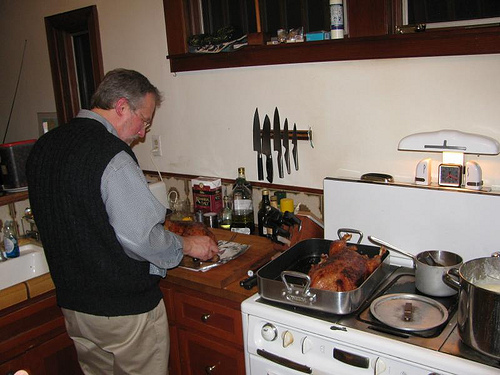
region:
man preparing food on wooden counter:
[23, 65, 243, 372]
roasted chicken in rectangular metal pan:
[257, 220, 390, 317]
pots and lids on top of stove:
[367, 229, 497, 371]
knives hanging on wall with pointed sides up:
[250, 105, 315, 185]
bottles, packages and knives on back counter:
[157, 170, 323, 245]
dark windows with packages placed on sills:
[160, 3, 499, 75]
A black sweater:
[41, 119, 112, 296]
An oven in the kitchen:
[277, 264, 382, 371]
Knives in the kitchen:
[241, 105, 301, 163]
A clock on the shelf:
[435, 164, 465, 190]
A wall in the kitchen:
[188, 81, 233, 141]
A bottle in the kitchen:
[227, 170, 252, 230]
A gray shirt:
[110, 166, 165, 257]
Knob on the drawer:
[190, 293, 214, 331]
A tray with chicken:
[245, 219, 382, 319]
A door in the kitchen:
[45, 24, 89, 106]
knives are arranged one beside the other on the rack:
[251, 106, 313, 184]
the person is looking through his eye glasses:
[25, 69, 220, 373]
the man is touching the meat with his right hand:
[27, 67, 219, 373]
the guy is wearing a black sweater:
[24, 68, 219, 373]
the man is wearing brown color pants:
[27, 67, 217, 373]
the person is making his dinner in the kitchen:
[4, 5, 497, 373]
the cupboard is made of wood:
[154, 276, 269, 373]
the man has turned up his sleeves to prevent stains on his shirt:
[27, 68, 219, 373]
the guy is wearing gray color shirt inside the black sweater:
[27, 69, 217, 373]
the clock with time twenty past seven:
[438, 161, 463, 187]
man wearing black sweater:
[21, 114, 151, 316]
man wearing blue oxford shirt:
[22, 107, 186, 317]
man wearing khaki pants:
[58, 298, 175, 371]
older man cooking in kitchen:
[12, 60, 240, 361]